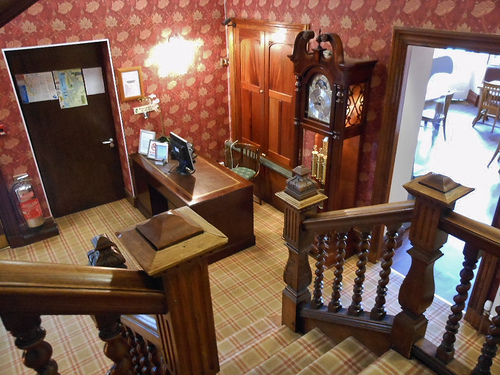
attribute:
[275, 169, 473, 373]
stair rail — antique, wooden, brown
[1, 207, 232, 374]
stair rail — antique, wooden, brown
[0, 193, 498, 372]
rug — brown, red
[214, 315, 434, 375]
rug — plaid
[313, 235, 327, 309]
railing — twisted, wooden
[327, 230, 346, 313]
railing — twisted, wooden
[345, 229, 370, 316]
railing — wooden, twisted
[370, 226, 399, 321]
railing — wooden, twisted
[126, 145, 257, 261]
desk — large, wooden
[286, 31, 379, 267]
grandfather clock — brown, old, large, decorative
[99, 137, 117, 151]
door knob — chrome, silver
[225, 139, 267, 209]
chair — wooden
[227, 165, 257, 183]
cushion — blue, green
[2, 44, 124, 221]
door — brown, wooden